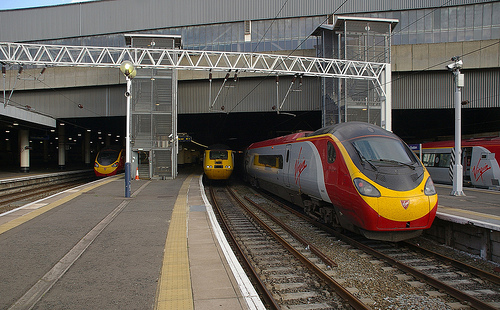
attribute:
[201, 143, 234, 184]
train — multi-colored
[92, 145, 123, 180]
train — multi-colored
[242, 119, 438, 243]
train — red, yellow, large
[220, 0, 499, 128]
electrical wires — hanging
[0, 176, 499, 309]
tracks — two sets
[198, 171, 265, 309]
line — white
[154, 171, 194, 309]
line — yellow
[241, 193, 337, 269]
line — broken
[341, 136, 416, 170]
windshield — large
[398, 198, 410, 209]
symbol — red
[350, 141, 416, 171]
windshield wiper — black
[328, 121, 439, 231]
front of train — sleek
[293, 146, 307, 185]
words — red